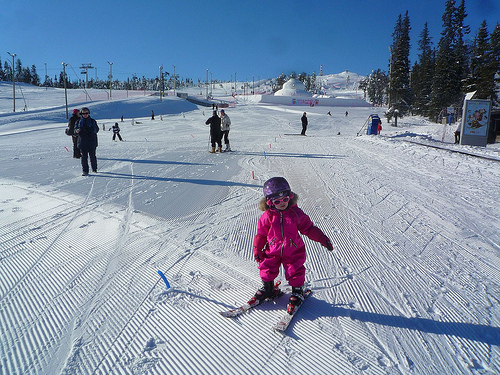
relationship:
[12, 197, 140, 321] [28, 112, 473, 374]
tracks in snow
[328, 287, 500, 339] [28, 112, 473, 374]
shadow in snow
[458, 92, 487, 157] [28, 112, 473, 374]
kiosk in snow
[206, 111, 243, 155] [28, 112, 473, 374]
people in snow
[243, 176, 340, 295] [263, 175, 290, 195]
kid wearing helmet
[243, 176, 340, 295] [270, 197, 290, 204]
child wearing glasses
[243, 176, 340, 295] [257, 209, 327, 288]
child wearing suit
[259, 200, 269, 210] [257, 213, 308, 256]
fur on coat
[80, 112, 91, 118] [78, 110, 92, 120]
glasses on face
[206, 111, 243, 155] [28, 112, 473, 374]
people ski in snow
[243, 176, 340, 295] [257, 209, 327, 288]
child wearing snowsuit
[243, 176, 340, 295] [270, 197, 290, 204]
girl wearing glasses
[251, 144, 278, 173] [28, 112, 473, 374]
ridges in snow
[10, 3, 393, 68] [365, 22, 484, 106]
sky above trees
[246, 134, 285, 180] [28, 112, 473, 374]
poles in snow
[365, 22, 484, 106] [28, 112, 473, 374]
trees in snow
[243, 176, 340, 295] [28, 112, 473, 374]
toddler in snow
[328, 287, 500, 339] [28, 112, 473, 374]
shadow on snow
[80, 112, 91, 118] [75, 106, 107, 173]
glasses on woman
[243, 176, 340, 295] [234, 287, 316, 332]
kid on skis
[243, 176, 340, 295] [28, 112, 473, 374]
kid plays in snow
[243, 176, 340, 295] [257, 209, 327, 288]
girl in snowsuit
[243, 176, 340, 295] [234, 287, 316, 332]
child riding skis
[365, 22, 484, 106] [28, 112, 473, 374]
trees are beside snow